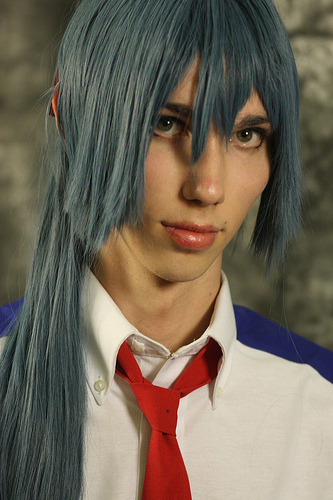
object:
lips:
[157, 214, 229, 253]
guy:
[0, 0, 332, 499]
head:
[49, 3, 291, 290]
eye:
[231, 104, 282, 155]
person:
[30, 3, 331, 498]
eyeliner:
[152, 102, 194, 122]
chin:
[138, 250, 228, 283]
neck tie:
[122, 336, 224, 498]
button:
[90, 377, 105, 394]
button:
[211, 380, 226, 400]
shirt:
[0, 274, 331, 495]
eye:
[145, 107, 191, 137]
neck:
[91, 225, 233, 360]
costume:
[9, 283, 325, 491]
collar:
[60, 269, 241, 411]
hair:
[63, 3, 298, 243]